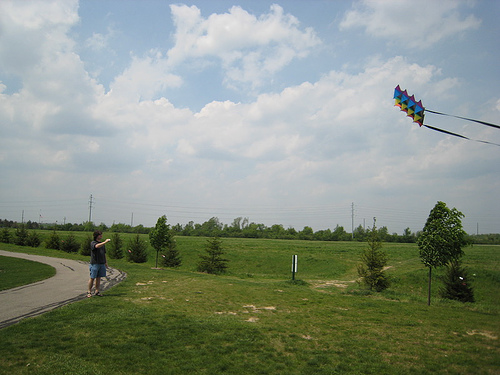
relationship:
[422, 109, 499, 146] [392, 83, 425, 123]
string on kite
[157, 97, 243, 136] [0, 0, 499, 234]
white clouds in sky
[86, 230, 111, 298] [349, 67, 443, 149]
man using string to fly kite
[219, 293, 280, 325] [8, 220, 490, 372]
dirt patch in grass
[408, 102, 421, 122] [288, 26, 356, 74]
colorful flying through sky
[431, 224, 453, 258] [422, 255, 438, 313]
leaves over trunk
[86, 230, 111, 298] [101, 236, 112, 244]
man has hand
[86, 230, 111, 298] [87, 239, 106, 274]
man wearing shirt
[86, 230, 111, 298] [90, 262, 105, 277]
man wearing shorts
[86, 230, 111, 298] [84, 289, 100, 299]
man wearing shoes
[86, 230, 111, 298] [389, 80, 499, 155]
man flying kite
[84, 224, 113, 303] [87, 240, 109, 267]
man wearing shirt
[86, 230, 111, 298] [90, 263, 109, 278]
man wearing shorts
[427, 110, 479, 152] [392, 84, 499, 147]
string attached to kite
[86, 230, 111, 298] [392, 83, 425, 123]
man flying kite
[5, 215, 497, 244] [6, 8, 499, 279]
line in background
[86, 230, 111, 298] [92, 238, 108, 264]
man in t-shirt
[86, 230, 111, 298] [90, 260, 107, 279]
man in shorts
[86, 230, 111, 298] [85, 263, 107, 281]
man wearing shorts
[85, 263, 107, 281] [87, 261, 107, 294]
shorts on legs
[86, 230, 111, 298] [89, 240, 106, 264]
man wearing shirt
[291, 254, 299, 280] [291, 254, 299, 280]
back sign on back sign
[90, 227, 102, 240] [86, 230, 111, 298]
head of man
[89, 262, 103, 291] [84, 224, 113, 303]
legs of man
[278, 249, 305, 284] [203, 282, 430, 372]
back sign in meadow